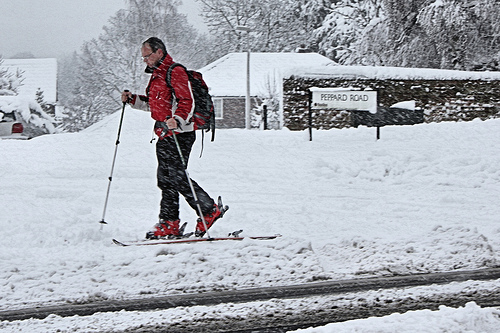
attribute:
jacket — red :
[129, 54, 201, 139]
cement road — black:
[2, 265, 494, 330]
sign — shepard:
[305, 66, 432, 148]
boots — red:
[151, 206, 238, 239]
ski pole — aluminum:
[94, 88, 130, 240]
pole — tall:
[245, 30, 251, 128]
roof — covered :
[175, 44, 335, 99]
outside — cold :
[1, 17, 378, 303]